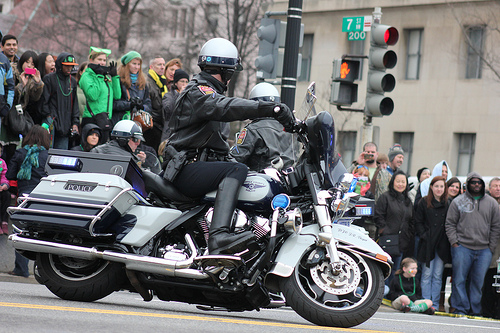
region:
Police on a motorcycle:
[10, 38, 392, 325]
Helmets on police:
[85, 35, 291, 141]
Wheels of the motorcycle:
[8, 174, 395, 329]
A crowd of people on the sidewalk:
[5, 34, 499, 254]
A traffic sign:
[367, 17, 401, 133]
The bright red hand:
[334, 56, 361, 83]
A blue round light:
[267, 192, 292, 209]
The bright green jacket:
[78, 67, 119, 113]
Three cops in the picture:
[92, 37, 305, 252]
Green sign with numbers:
[339, 14, 371, 41]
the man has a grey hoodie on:
[456, 176, 493, 251]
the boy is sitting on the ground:
[401, 252, 418, 311]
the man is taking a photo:
[362, 142, 374, 164]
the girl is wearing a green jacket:
[68, 46, 127, 118]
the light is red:
[376, 22, 400, 50]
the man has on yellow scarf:
[143, 56, 172, 94]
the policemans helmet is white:
[201, 38, 254, 72]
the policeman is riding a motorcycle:
[30, 178, 367, 321]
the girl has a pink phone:
[20, 63, 40, 78]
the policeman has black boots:
[199, 174, 259, 258]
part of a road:
[51, 309, 76, 320]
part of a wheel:
[284, 274, 308, 297]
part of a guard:
[361, 243, 404, 258]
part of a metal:
[123, 252, 158, 273]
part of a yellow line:
[182, 304, 213, 324]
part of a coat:
[223, 102, 255, 127]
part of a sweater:
[453, 207, 482, 244]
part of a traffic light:
[350, 70, 389, 115]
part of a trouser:
[186, 167, 225, 179]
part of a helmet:
[206, 35, 233, 69]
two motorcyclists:
[51, 30, 420, 315]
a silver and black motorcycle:
[45, 142, 377, 322]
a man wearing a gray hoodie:
[451, 169, 498, 249]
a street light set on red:
[367, 15, 409, 120]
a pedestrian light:
[329, 51, 367, 118]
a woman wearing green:
[86, 37, 125, 115]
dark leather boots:
[212, 167, 266, 267]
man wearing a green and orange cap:
[58, 47, 79, 86]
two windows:
[401, 0, 497, 97]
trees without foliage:
[41, 0, 261, 36]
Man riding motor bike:
[5, 37, 378, 327]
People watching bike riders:
[0, 52, 173, 159]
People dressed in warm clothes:
[378, 160, 497, 312]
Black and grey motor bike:
[11, 153, 378, 323]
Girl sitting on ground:
[392, 257, 434, 317]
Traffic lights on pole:
[364, 23, 401, 125]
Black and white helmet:
[196, 35, 243, 80]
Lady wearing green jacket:
[78, 48, 115, 117]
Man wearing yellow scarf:
[148, 57, 168, 96]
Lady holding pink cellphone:
[18, 47, 41, 80]